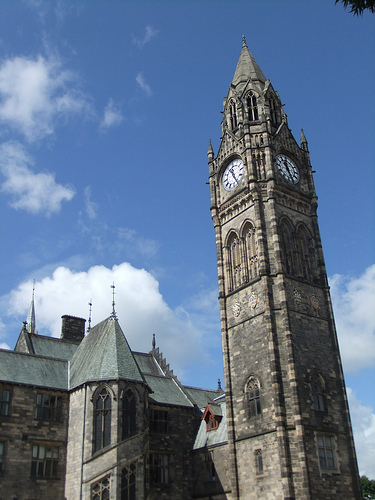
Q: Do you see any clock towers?
A: Yes, there is a clock tower.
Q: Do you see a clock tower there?
A: Yes, there is a clock tower.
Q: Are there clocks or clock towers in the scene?
A: Yes, there is a clock tower.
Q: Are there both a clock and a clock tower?
A: Yes, there are both a clock tower and a clock.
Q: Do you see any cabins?
A: No, there are no cabins.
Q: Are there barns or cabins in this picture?
A: No, there are no cabins or barns.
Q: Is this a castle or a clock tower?
A: This is a clock tower.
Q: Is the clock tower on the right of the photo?
A: Yes, the clock tower is on the right of the image.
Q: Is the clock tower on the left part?
A: No, the clock tower is on the right of the image.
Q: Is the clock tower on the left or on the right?
A: The clock tower is on the right of the image.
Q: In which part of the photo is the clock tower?
A: The clock tower is on the right of the image.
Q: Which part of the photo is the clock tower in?
A: The clock tower is on the right of the image.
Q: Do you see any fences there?
A: No, there are no fences.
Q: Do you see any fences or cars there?
A: No, there are no fences or cars.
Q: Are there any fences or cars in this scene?
A: No, there are no fences or cars.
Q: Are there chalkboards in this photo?
A: No, there are no chalkboards.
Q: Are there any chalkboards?
A: No, there are no chalkboards.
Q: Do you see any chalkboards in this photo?
A: No, there are no chalkboards.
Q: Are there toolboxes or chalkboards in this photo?
A: No, there are no chalkboards or toolboxes.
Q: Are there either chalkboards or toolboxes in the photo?
A: No, there are no chalkboards or toolboxes.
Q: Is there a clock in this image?
A: Yes, there is a clock.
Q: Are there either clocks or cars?
A: Yes, there is a clock.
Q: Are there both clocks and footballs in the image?
A: No, there is a clock but no footballs.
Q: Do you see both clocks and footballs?
A: No, there is a clock but no footballs.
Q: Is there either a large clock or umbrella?
A: Yes, there is a large clock.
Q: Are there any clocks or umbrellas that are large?
A: Yes, the clock is large.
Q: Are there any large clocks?
A: Yes, there is a large clock.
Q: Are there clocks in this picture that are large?
A: Yes, there is a large clock.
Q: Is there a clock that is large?
A: Yes, there is a clock that is large.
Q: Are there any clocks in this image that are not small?
A: Yes, there is a large clock.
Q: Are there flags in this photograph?
A: No, there are no flags.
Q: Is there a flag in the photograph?
A: No, there are no flags.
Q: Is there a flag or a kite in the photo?
A: No, there are no flags or kites.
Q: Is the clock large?
A: Yes, the clock is large.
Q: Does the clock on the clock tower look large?
A: Yes, the clock is large.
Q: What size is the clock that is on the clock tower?
A: The clock is large.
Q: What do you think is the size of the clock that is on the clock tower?
A: The clock is large.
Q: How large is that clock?
A: The clock is large.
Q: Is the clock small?
A: No, the clock is large.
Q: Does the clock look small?
A: No, the clock is large.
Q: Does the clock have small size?
A: No, the clock is large.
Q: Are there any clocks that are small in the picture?
A: No, there is a clock but it is large.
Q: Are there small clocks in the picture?
A: No, there is a clock but it is large.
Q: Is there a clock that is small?
A: No, there is a clock but it is large.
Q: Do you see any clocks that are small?
A: No, there is a clock but it is large.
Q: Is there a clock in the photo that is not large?
A: No, there is a clock but it is large.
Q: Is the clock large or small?
A: The clock is large.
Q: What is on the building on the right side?
A: The clock is on the clock tower.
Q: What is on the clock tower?
A: The clock is on the clock tower.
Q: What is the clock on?
A: The clock is on the clock tower.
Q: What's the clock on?
A: The clock is on the clock tower.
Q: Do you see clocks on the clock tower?
A: Yes, there is a clock on the clock tower.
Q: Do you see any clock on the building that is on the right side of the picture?
A: Yes, there is a clock on the clock tower.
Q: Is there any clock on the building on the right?
A: Yes, there is a clock on the clock tower.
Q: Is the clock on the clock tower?
A: Yes, the clock is on the clock tower.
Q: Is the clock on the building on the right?
A: Yes, the clock is on the clock tower.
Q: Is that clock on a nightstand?
A: No, the clock is on the clock tower.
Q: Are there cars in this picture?
A: No, there are no cars.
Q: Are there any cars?
A: No, there are no cars.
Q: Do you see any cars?
A: No, there are no cars.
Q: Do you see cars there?
A: No, there are no cars.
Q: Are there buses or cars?
A: No, there are no cars or buses.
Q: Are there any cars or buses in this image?
A: No, there are no cars or buses.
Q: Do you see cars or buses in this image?
A: No, there are no cars or buses.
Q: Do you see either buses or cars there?
A: No, there are no cars or buses.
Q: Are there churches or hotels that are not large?
A: No, there is a church but it is large.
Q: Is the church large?
A: Yes, the church is large.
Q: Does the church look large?
A: Yes, the church is large.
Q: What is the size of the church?
A: The church is large.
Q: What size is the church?
A: The church is large.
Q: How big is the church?
A: The church is large.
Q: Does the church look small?
A: No, the church is large.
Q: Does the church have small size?
A: No, the church is large.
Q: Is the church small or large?
A: The church is large.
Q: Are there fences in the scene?
A: No, there are no fences.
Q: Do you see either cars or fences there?
A: No, there are no fences or cars.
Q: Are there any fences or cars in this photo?
A: No, there are no fences or cars.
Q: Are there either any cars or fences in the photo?
A: No, there are no fences or cars.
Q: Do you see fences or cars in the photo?
A: No, there are no fences or cars.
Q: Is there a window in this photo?
A: Yes, there is a window.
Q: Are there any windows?
A: Yes, there is a window.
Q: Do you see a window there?
A: Yes, there is a window.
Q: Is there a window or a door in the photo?
A: Yes, there is a window.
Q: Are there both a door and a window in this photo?
A: No, there is a window but no doors.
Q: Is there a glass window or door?
A: Yes, there is a glass window.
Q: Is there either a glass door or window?
A: Yes, there is a glass window.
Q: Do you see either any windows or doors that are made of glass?
A: Yes, the window is made of glass.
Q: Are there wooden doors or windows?
A: Yes, there is a wood window.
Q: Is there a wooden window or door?
A: Yes, there is a wood window.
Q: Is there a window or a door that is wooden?
A: Yes, the window is wooden.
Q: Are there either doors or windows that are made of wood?
A: Yes, the window is made of wood.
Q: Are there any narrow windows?
A: Yes, there is a narrow window.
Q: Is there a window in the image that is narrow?
A: Yes, there is a window that is narrow.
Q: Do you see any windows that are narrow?
A: Yes, there is a window that is narrow.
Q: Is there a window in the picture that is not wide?
A: Yes, there is a narrow window.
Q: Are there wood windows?
A: Yes, there is a window that is made of wood.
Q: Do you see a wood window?
A: Yes, there is a window that is made of wood.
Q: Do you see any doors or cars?
A: No, there are no cars or doors.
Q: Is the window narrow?
A: Yes, the window is narrow.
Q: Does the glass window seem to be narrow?
A: Yes, the window is narrow.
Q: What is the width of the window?
A: The window is narrow.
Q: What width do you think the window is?
A: The window is narrow.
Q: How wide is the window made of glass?
A: The window is narrow.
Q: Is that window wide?
A: No, the window is narrow.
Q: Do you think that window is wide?
A: No, the window is narrow.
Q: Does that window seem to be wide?
A: No, the window is narrow.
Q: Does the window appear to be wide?
A: No, the window is narrow.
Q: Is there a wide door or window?
A: No, there is a window but it is narrow.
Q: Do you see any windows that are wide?
A: No, there is a window but it is narrow.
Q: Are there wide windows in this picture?
A: No, there is a window but it is narrow.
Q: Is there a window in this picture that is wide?
A: No, there is a window but it is narrow.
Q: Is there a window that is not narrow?
A: No, there is a window but it is narrow.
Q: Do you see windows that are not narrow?
A: No, there is a window but it is narrow.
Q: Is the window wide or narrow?
A: The window is narrow.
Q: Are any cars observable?
A: No, there are no cars.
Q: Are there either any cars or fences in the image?
A: No, there are no cars or fences.